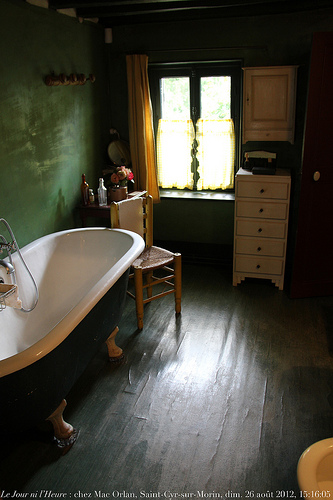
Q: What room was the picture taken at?
A: It was taken at the bathroom.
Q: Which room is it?
A: It is a bathroom.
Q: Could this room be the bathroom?
A: Yes, it is the bathroom.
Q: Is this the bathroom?
A: Yes, it is the bathroom.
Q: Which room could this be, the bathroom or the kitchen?
A: It is the bathroom.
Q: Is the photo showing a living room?
A: No, the picture is showing a bathroom.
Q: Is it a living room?
A: No, it is a bathroom.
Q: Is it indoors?
A: Yes, it is indoors.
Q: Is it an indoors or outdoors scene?
A: It is indoors.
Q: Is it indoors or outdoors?
A: It is indoors.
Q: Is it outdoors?
A: No, it is indoors.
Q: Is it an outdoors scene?
A: No, it is indoors.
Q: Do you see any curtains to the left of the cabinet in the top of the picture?
A: Yes, there is a curtain to the left of the cabinet.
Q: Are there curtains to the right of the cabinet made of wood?
A: No, the curtain is to the left of the cabinet.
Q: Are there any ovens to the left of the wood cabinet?
A: No, there is a curtain to the left of the cabinet.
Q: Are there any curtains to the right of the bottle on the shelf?
A: Yes, there is a curtain to the right of the bottle.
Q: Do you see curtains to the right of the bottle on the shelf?
A: Yes, there is a curtain to the right of the bottle.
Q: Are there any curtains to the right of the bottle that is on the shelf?
A: Yes, there is a curtain to the right of the bottle.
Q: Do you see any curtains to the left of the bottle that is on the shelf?
A: No, the curtain is to the right of the bottle.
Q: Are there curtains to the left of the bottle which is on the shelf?
A: No, the curtain is to the right of the bottle.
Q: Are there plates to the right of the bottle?
A: No, there is a curtain to the right of the bottle.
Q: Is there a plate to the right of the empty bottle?
A: No, there is a curtain to the right of the bottle.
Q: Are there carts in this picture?
A: No, there are no carts.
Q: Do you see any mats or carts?
A: No, there are no carts or mats.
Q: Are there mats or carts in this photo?
A: No, there are no carts or mats.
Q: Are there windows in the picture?
A: Yes, there is a window.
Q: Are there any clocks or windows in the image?
A: Yes, there is a window.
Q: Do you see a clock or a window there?
A: Yes, there is a window.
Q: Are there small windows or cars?
A: Yes, there is a small window.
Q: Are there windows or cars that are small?
A: Yes, the window is small.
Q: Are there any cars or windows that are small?
A: Yes, the window is small.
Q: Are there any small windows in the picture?
A: Yes, there is a small window.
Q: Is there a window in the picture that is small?
A: Yes, there is a window that is small.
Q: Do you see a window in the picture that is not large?
A: Yes, there is a small window.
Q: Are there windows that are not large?
A: Yes, there is a small window.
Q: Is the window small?
A: Yes, the window is small.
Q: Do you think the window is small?
A: Yes, the window is small.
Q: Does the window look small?
A: Yes, the window is small.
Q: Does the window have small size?
A: Yes, the window is small.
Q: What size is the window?
A: The window is small.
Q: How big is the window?
A: The window is small.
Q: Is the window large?
A: No, the window is small.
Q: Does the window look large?
A: No, the window is small.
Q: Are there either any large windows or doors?
A: No, there is a window but it is small.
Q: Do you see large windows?
A: No, there is a window but it is small.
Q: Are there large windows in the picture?
A: No, there is a window but it is small.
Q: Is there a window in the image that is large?
A: No, there is a window but it is small.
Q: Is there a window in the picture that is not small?
A: No, there is a window but it is small.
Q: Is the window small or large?
A: The window is small.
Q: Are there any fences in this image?
A: No, there are no fences.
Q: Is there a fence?
A: No, there are no fences.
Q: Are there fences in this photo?
A: No, there are no fences.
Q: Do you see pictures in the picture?
A: No, there are no pictures.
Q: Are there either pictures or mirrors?
A: No, there are no pictures or mirrors.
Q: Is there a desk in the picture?
A: No, there are no desks.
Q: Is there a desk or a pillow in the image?
A: No, there are no desks or pillows.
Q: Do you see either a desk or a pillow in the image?
A: No, there are no desks or pillows.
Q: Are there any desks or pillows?
A: No, there are no desks or pillows.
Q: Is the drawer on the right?
A: Yes, the drawer is on the right of the image.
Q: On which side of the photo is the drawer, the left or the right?
A: The drawer is on the right of the image.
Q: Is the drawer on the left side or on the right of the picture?
A: The drawer is on the right of the image.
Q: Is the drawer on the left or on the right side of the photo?
A: The drawer is on the right of the image.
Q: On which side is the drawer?
A: The drawer is on the right of the image.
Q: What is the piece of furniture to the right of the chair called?
A: The piece of furniture is a drawer.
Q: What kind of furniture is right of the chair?
A: The piece of furniture is a drawer.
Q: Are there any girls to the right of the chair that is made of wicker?
A: No, there is a drawer to the right of the chair.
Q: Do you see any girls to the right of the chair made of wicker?
A: No, there is a drawer to the right of the chair.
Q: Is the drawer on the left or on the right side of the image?
A: The drawer is on the right of the image.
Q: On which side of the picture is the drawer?
A: The drawer is on the right of the image.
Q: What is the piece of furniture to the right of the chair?
A: The piece of furniture is a drawer.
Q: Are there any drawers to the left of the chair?
A: No, the drawer is to the right of the chair.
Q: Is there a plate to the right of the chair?
A: No, there is a drawer to the right of the chair.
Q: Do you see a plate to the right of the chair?
A: No, there is a drawer to the right of the chair.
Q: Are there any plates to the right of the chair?
A: No, there is a drawer to the right of the chair.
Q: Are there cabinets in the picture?
A: Yes, there is a cabinet.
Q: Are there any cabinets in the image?
A: Yes, there is a cabinet.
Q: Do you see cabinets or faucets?
A: Yes, there is a cabinet.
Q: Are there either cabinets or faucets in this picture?
A: Yes, there is a cabinet.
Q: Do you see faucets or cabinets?
A: Yes, there is a cabinet.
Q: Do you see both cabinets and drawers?
A: Yes, there are both a cabinet and a drawer.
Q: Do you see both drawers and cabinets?
A: Yes, there are both a cabinet and a drawer.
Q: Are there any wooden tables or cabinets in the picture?
A: Yes, there is a wood cabinet.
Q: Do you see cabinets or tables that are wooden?
A: Yes, the cabinet is wooden.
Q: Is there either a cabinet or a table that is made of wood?
A: Yes, the cabinet is made of wood.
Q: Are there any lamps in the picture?
A: No, there are no lamps.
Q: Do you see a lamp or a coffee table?
A: No, there are no lamps or coffee tables.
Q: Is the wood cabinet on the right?
A: Yes, the cabinet is on the right of the image.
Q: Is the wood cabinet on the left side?
A: No, the cabinet is on the right of the image.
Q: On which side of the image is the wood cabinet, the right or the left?
A: The cabinet is on the right of the image.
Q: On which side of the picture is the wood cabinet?
A: The cabinet is on the right of the image.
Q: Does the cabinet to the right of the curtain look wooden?
A: Yes, the cabinet is wooden.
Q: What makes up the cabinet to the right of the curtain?
A: The cabinet is made of wood.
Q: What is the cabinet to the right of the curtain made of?
A: The cabinet is made of wood.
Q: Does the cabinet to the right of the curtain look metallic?
A: No, the cabinet is wooden.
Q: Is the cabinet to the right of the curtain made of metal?
A: No, the cabinet is made of wood.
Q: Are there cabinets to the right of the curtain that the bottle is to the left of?
A: Yes, there is a cabinet to the right of the curtain.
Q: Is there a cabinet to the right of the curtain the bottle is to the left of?
A: Yes, there is a cabinet to the right of the curtain.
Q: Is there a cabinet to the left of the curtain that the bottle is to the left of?
A: No, the cabinet is to the right of the curtain.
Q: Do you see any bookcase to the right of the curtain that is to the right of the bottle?
A: No, there is a cabinet to the right of the curtain.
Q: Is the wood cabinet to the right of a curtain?
A: Yes, the cabinet is to the right of a curtain.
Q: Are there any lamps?
A: No, there are no lamps.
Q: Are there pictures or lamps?
A: No, there are no lamps or pictures.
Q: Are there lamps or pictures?
A: No, there are no lamps or pictures.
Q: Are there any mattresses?
A: No, there are no mattresses.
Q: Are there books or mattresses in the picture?
A: No, there are no mattresses or books.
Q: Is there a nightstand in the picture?
A: No, there are no nightstands.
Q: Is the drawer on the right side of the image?
A: Yes, the drawer is on the right of the image.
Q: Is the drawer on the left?
A: No, the drawer is on the right of the image.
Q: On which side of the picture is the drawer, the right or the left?
A: The drawer is on the right of the image.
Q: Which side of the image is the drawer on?
A: The drawer is on the right of the image.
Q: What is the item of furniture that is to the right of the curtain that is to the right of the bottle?
A: The piece of furniture is a drawer.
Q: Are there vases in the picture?
A: No, there are no vases.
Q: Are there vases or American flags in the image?
A: No, there are no vases or American flags.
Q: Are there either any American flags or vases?
A: No, there are no vases or American flags.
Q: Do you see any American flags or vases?
A: No, there are no vases or American flags.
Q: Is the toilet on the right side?
A: Yes, the toilet is on the right of the image.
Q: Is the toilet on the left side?
A: No, the toilet is on the right of the image.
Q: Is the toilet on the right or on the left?
A: The toilet is on the right of the image.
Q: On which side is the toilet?
A: The toilet is on the right of the image.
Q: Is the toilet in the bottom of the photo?
A: Yes, the toilet is in the bottom of the image.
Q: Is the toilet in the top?
A: No, the toilet is in the bottom of the image.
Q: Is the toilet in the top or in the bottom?
A: The toilet is in the bottom of the image.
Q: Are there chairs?
A: Yes, there is a chair.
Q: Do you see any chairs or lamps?
A: Yes, there is a chair.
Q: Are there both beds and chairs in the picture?
A: No, there is a chair but no beds.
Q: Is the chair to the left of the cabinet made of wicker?
A: Yes, the chair is made of wicker.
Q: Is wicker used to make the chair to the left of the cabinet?
A: Yes, the chair is made of wicker.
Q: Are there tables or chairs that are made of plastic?
A: No, there is a chair but it is made of wicker.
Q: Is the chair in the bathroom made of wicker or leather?
A: The chair is made of wicker.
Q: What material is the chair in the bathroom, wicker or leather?
A: The chair is made of wicker.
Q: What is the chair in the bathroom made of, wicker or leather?
A: The chair is made of wicker.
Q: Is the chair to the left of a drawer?
A: Yes, the chair is to the left of a drawer.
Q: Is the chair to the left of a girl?
A: No, the chair is to the left of a drawer.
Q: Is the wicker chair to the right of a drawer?
A: No, the chair is to the left of a drawer.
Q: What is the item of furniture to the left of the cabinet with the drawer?
A: The piece of furniture is a chair.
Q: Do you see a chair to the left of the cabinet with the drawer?
A: Yes, there is a chair to the left of the cabinet.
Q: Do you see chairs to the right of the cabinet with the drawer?
A: No, the chair is to the left of the cabinet.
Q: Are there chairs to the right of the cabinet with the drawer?
A: No, the chair is to the left of the cabinet.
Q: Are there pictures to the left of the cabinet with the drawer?
A: No, there is a chair to the left of the cabinet.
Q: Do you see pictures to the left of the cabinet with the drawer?
A: No, there is a chair to the left of the cabinet.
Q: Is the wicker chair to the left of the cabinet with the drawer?
A: Yes, the chair is to the left of the cabinet.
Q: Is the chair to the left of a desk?
A: No, the chair is to the left of the cabinet.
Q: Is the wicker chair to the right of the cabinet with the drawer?
A: No, the chair is to the left of the cabinet.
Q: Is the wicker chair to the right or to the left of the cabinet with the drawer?
A: The chair is to the left of the cabinet.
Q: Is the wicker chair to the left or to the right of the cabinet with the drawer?
A: The chair is to the left of the cabinet.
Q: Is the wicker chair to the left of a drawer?
A: Yes, the chair is to the left of a drawer.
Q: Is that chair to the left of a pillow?
A: No, the chair is to the left of a drawer.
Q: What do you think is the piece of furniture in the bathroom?
A: The piece of furniture is a chair.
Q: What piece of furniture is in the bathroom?
A: The piece of furniture is a chair.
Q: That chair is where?
A: The chair is in the bathroom.